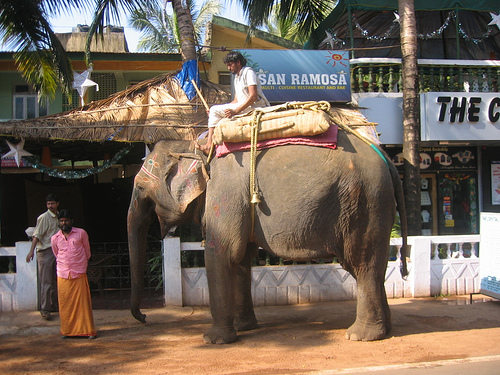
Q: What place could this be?
A: It is a store.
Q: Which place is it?
A: It is a store.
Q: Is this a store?
A: Yes, it is a store.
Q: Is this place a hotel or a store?
A: It is a store.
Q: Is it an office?
A: No, it is a store.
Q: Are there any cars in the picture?
A: No, there are no cars.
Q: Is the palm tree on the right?
A: Yes, the palm tree is on the right of the image.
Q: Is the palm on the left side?
A: No, the palm is on the right of the image.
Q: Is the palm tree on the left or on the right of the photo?
A: The palm tree is on the right of the image.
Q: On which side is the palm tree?
A: The palm tree is on the right of the image.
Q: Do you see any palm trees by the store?
A: Yes, there is a palm tree by the store.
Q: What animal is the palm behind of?
A: The palm is behind the elephant.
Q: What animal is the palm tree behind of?
A: The palm is behind the elephant.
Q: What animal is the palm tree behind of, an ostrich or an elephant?
A: The palm tree is behind an elephant.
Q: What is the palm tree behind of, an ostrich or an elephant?
A: The palm tree is behind an elephant.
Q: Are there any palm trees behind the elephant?
A: Yes, there is a palm tree behind the elephant.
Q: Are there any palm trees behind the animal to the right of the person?
A: Yes, there is a palm tree behind the elephant.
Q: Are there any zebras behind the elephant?
A: No, there is a palm tree behind the elephant.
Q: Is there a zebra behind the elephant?
A: No, there is a palm tree behind the elephant.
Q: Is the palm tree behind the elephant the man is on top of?
A: Yes, the palm tree is behind the elephant.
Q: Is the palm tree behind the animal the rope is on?
A: Yes, the palm tree is behind the elephant.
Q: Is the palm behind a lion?
A: No, the palm is behind the elephant.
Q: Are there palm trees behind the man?
A: Yes, there is a palm tree behind the man.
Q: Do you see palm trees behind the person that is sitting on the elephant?
A: Yes, there is a palm tree behind the man.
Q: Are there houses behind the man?
A: No, there is a palm tree behind the man.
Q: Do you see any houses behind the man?
A: No, there is a palm tree behind the man.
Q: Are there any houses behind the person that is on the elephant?
A: No, there is a palm tree behind the man.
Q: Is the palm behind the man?
A: Yes, the palm is behind the man.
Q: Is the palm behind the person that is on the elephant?
A: Yes, the palm is behind the man.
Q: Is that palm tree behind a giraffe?
A: No, the palm tree is behind the man.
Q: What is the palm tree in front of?
A: The palm tree is in front of the store.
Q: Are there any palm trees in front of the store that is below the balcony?
A: Yes, there is a palm tree in front of the store.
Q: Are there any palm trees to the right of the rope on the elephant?
A: Yes, there is a palm tree to the right of the rope.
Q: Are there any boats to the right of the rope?
A: No, there is a palm tree to the right of the rope.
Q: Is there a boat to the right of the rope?
A: No, there is a palm tree to the right of the rope.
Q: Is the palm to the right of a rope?
A: Yes, the palm is to the right of a rope.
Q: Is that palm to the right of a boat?
A: No, the palm is to the right of a rope.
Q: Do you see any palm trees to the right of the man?
A: Yes, there is a palm tree to the right of the man.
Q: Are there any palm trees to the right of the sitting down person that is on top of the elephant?
A: Yes, there is a palm tree to the right of the man.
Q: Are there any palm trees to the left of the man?
A: No, the palm tree is to the right of the man.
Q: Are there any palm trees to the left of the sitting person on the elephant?
A: No, the palm tree is to the right of the man.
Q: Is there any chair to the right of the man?
A: No, there is a palm tree to the right of the man.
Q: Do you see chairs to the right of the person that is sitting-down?
A: No, there is a palm tree to the right of the man.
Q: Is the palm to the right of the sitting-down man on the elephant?
A: Yes, the palm is to the right of the man.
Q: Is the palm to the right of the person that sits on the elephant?
A: Yes, the palm is to the right of the man.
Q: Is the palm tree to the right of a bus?
A: No, the palm tree is to the right of the man.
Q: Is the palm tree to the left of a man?
A: No, the palm tree is to the right of a man.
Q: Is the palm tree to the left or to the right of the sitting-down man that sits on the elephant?
A: The palm tree is to the right of the man.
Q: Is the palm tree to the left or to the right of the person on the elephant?
A: The palm tree is to the right of the man.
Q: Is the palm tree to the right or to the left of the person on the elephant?
A: The palm tree is to the right of the man.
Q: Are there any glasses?
A: No, there are no glasses.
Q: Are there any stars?
A: Yes, there is a star.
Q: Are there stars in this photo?
A: Yes, there is a star.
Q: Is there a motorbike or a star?
A: Yes, there is a star.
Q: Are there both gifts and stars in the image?
A: No, there is a star but no gifts.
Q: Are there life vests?
A: No, there are no life vests.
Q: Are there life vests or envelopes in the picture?
A: No, there are no life vests or envelopes.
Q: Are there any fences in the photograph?
A: Yes, there is a fence.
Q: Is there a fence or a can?
A: Yes, there is a fence.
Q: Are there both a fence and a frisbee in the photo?
A: No, there is a fence but no frisbees.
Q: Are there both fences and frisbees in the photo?
A: No, there is a fence but no frisbees.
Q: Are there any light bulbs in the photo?
A: No, there are no light bulbs.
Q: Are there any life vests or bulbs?
A: No, there are no bulbs or life vests.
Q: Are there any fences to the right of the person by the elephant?
A: Yes, there is a fence to the right of the person.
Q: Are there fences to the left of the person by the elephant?
A: No, the fence is to the right of the person.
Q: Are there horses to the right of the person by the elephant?
A: No, there is a fence to the right of the person.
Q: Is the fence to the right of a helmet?
A: No, the fence is to the right of a person.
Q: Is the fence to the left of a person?
A: No, the fence is to the right of a person.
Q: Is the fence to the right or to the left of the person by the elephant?
A: The fence is to the right of the person.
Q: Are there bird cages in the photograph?
A: No, there are no bird cages.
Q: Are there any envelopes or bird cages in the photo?
A: No, there are no bird cages or envelopes.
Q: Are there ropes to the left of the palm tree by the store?
A: Yes, there is a rope to the left of the palm tree.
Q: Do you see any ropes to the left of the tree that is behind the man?
A: Yes, there is a rope to the left of the palm tree.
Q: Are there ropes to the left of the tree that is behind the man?
A: Yes, there is a rope to the left of the palm tree.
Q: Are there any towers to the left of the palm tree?
A: No, there is a rope to the left of the palm tree.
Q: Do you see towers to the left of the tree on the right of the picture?
A: No, there is a rope to the left of the palm tree.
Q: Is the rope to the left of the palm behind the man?
A: Yes, the rope is to the left of the palm tree.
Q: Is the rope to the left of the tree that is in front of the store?
A: Yes, the rope is to the left of the palm tree.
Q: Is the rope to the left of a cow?
A: No, the rope is to the left of the palm tree.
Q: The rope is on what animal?
A: The rope is on the elephant.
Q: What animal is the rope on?
A: The rope is on the elephant.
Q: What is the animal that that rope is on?
A: The animal is an elephant.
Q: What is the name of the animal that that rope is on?
A: The animal is an elephant.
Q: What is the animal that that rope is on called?
A: The animal is an elephant.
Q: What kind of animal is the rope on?
A: The rope is on the elephant.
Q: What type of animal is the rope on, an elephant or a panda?
A: The rope is on an elephant.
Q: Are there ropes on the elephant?
A: Yes, there is a rope on the elephant.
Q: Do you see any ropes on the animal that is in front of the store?
A: Yes, there is a rope on the elephant.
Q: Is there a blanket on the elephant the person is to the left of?
A: No, there is a rope on the elephant.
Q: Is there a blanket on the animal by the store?
A: No, there is a rope on the elephant.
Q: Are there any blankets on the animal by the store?
A: No, there is a rope on the elephant.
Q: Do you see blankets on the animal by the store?
A: No, there is a rope on the elephant.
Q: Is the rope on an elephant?
A: Yes, the rope is on an elephant.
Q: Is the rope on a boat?
A: No, the rope is on an elephant.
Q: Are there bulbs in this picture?
A: No, there are no bulbs.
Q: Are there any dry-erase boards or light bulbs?
A: No, there are no light bulbs or dry-erase boards.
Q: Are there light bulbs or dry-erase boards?
A: No, there are no light bulbs or dry-erase boards.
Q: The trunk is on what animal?
A: The trunk is on the elephant.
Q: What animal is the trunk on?
A: The trunk is on the elephant.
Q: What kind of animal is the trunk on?
A: The trunk is on the elephant.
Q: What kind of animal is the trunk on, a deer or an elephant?
A: The trunk is on an elephant.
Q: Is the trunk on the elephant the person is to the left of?
A: Yes, the trunk is on the elephant.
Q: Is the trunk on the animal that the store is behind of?
A: Yes, the trunk is on the elephant.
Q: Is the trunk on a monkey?
A: No, the trunk is on the elephant.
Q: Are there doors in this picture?
A: Yes, there is a door.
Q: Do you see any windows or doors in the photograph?
A: Yes, there is a door.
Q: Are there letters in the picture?
A: Yes, there are letters.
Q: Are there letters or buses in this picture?
A: Yes, there are letters.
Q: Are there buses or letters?
A: Yes, there are letters.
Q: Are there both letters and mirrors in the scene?
A: No, there are letters but no mirrors.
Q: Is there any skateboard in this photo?
A: No, there are no skateboards.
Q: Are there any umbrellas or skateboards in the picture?
A: No, there are no skateboards or umbrellas.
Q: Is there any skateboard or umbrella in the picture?
A: No, there are no skateboards or umbrellas.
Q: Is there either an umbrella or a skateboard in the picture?
A: No, there are no skateboards or umbrellas.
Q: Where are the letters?
A: The letters are on the store.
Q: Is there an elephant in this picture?
A: Yes, there is an elephant.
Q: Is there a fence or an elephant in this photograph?
A: Yes, there is an elephant.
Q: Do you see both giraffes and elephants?
A: No, there is an elephant but no giraffes.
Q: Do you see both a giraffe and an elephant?
A: No, there is an elephant but no giraffes.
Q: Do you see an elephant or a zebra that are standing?
A: Yes, the elephant is standing.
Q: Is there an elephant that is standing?
A: Yes, there is an elephant that is standing.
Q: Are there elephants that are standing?
A: Yes, there is an elephant that is standing.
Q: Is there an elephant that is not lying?
A: Yes, there is an elephant that is standing.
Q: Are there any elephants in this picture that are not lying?
A: Yes, there is an elephant that is standing.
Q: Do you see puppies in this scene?
A: No, there are no puppies.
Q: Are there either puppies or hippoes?
A: No, there are no puppies or hippoes.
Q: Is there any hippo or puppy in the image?
A: No, there are no puppies or hippoes.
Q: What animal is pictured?
A: The animal is an elephant.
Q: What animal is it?
A: The animal is an elephant.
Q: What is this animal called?
A: This is an elephant.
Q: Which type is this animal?
A: This is an elephant.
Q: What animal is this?
A: This is an elephant.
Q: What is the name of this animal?
A: This is an elephant.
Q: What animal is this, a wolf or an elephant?
A: This is an elephant.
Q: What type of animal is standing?
A: The animal is an elephant.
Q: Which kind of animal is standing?
A: The animal is an elephant.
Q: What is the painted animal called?
A: The animal is an elephant.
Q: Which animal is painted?
A: The animal is an elephant.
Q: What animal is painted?
A: The animal is an elephant.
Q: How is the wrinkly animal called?
A: The animal is an elephant.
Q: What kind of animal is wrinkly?
A: The animal is an elephant.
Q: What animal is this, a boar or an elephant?
A: This is an elephant.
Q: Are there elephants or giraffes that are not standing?
A: No, there is an elephant but it is standing.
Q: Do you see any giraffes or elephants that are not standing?
A: No, there is an elephant but it is standing.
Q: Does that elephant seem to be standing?
A: Yes, the elephant is standing.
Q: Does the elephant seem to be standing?
A: Yes, the elephant is standing.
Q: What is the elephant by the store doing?
A: The elephant is standing.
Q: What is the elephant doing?
A: The elephant is standing.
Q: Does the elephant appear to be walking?
A: No, the elephant is standing.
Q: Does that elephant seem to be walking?
A: No, the elephant is standing.